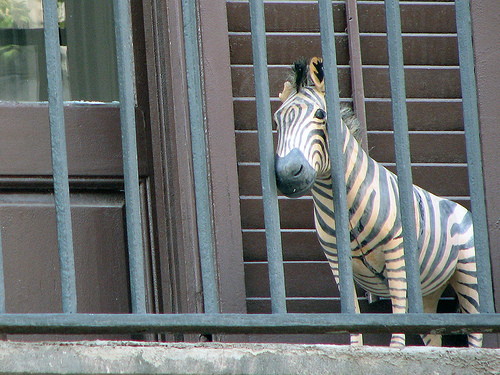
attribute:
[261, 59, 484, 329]
zebra — black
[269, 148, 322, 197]
nose — black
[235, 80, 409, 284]
statue — small, animal statue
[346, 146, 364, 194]
stripes — black, white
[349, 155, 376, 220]
stripes — black, white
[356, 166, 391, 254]
stripes — black, white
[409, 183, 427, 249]
stripes — black, white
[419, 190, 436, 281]
stripes — black, white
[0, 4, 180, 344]
door — brown, wooden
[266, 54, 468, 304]
statue — animal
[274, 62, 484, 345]
statue — miniature, zebra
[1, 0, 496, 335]
fence — metal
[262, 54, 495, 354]
zebra statue — small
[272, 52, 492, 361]
zebra — black, white, statue, striped, looking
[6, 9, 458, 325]
bars — blue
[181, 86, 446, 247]
zebra — replica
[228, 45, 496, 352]
statue — white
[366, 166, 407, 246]
stripe — black